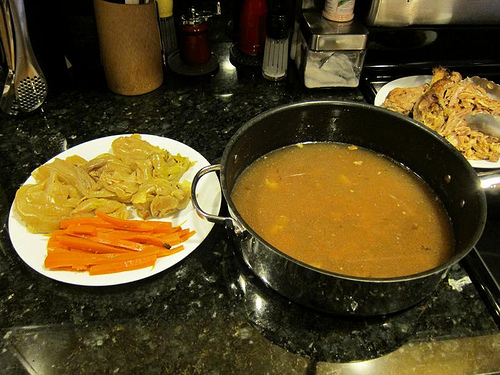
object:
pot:
[189, 101, 488, 323]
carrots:
[45, 214, 196, 277]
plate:
[7, 133, 222, 289]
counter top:
[0, 73, 500, 374]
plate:
[373, 72, 499, 171]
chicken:
[399, 66, 499, 115]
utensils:
[0, 0, 49, 118]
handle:
[190, 163, 228, 229]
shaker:
[263, 17, 289, 84]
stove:
[364, 24, 498, 81]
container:
[294, 14, 368, 92]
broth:
[262, 163, 454, 239]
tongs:
[463, 71, 499, 137]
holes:
[7, 74, 46, 115]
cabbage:
[27, 146, 178, 206]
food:
[36, 150, 183, 262]